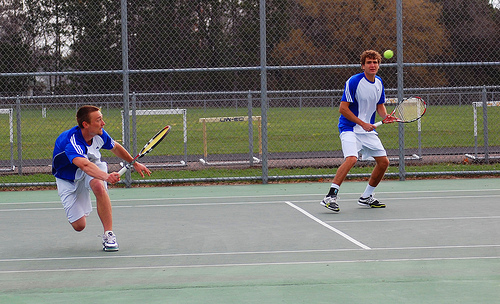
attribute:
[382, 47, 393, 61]
ball — yellow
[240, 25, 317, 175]
metal pole — tall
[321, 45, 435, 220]
guy — Poised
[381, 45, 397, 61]
tennis ball — Green 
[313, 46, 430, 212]
man — young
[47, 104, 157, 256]
guy — playing tennis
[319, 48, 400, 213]
guy — playing tennis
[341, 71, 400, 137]
shirt — white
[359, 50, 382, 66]
hair — brown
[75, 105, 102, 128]
hair — brown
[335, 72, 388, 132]
shirt — blue and white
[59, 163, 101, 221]
shorts — white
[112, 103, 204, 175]
racket — tennis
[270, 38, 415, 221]
man — in white and blue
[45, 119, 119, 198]
shirt — blue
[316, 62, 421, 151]
shirt — blue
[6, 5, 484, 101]
forest — dark